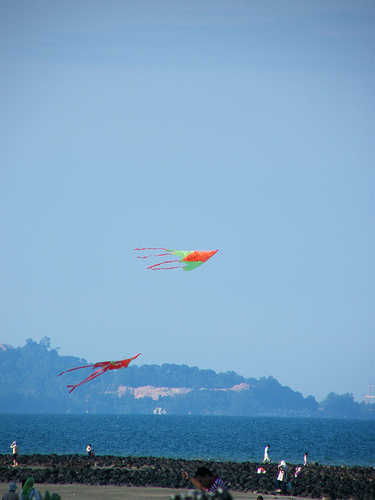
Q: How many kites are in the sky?
A: 2.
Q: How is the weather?
A: Clear.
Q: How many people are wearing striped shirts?
A: One.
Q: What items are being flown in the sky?
A: Kites.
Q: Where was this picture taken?
A: Beach.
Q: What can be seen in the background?
A: Hills.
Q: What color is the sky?
A: Blue.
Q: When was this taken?
A: Daytime.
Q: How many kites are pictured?
A: Two.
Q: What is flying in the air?
A: Kites.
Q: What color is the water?
A: Blue.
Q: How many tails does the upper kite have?
A: Four.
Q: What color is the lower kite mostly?
A: Red.